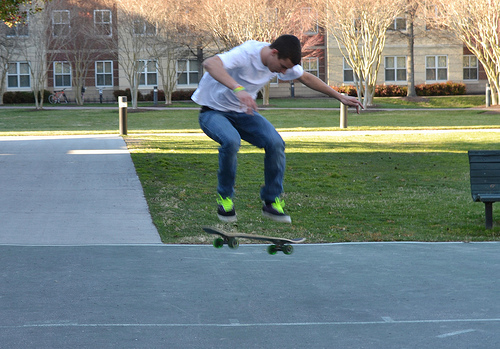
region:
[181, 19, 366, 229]
person wearing blue jeans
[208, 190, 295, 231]
person wearing pair of sneakers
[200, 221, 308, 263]
skate board in mid air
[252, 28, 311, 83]
head of a person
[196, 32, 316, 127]
person wearing t shirt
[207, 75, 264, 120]
hand of a person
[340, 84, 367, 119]
hand of a person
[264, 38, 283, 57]
ear of a person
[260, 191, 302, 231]
a sneaker worn by a person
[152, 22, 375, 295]
person jumping off from skateboard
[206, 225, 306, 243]
black and white skate board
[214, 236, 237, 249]
black tires on skate board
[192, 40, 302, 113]
white cotton tee shirt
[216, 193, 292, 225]
black and white skate shoes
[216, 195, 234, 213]
green laces on sneakers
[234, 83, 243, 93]
yellow band on wrist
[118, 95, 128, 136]
wood pole in ground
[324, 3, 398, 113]
tree with no leaves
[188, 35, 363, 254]
man jumping on skate board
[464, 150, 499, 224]
grey wooden park bench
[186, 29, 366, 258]
Skateboarder performing a trick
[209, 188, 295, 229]
Black sneakers with green shoelaces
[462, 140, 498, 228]
The end of a bench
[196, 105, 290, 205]
A pair of blue jeans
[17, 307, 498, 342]
White lines on the pavement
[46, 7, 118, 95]
Four windows on a building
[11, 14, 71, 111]
A tree with no leaves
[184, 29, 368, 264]
The skateboarder is up in the air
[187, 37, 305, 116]
A shirt is white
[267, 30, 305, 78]
Man has dark brown hair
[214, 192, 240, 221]
man wearing blue shoes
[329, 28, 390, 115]
tree near a sidewalk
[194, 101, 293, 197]
man wearing blue jeans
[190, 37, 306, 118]
man wearing a white tee shirt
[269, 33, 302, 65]
man with black hair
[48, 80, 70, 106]
bike leaning on the house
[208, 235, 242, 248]
skateboard with green wheels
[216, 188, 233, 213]
green shoe laces on sneakers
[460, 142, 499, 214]
bench in the park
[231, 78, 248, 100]
green wrist band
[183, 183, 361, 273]
man on a skateboard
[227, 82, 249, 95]
man with a band on his wrist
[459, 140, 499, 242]
bench in a park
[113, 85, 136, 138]
Light pole in the ground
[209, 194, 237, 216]
green shoe laces in the man sneakers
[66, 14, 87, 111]
tree in front of a building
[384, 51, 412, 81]
window on a building